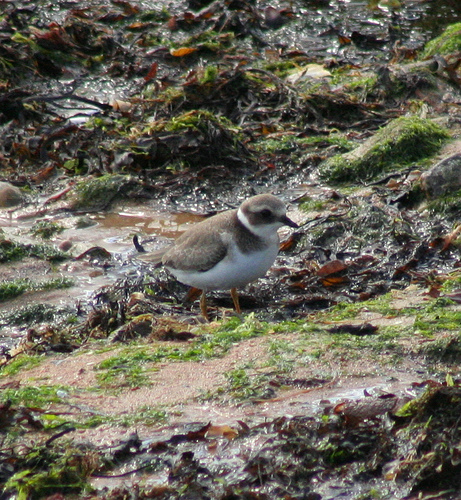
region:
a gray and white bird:
[124, 162, 379, 314]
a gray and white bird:
[144, 197, 324, 339]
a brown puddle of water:
[108, 191, 175, 239]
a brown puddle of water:
[118, 177, 190, 265]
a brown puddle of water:
[84, 193, 212, 266]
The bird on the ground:
[127, 190, 305, 321]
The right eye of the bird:
[256, 202, 276, 222]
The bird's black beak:
[278, 211, 304, 229]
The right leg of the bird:
[196, 289, 213, 324]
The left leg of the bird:
[228, 286, 246, 314]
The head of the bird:
[237, 193, 302, 239]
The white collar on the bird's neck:
[237, 204, 276, 238]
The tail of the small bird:
[128, 229, 168, 273]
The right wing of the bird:
[162, 226, 227, 277]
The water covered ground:
[1, 1, 458, 499]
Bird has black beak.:
[280, 202, 297, 237]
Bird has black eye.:
[258, 206, 273, 217]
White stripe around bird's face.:
[253, 201, 290, 222]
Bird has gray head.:
[253, 189, 278, 197]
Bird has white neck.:
[247, 218, 297, 245]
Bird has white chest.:
[238, 257, 271, 287]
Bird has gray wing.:
[176, 233, 218, 275]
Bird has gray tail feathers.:
[136, 246, 166, 280]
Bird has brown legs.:
[195, 299, 266, 314]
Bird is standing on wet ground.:
[166, 268, 274, 356]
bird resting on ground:
[145, 189, 303, 311]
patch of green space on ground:
[107, 353, 149, 378]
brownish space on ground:
[217, 442, 337, 490]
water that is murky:
[97, 211, 182, 232]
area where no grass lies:
[161, 366, 213, 387]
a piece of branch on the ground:
[18, 90, 107, 115]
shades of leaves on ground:
[134, 45, 204, 77]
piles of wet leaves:
[247, 3, 420, 58]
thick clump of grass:
[316, 117, 453, 169]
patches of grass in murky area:
[5, 224, 90, 306]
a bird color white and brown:
[127, 189, 310, 321]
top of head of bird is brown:
[241, 184, 303, 225]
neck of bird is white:
[234, 210, 263, 237]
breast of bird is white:
[204, 233, 285, 300]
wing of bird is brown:
[149, 217, 226, 274]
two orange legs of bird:
[191, 284, 245, 324]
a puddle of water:
[4, 162, 229, 307]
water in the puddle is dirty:
[54, 185, 187, 275]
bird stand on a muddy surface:
[6, 6, 450, 488]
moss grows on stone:
[300, 97, 448, 197]